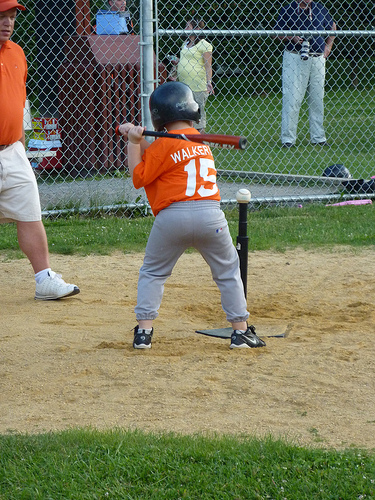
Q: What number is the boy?
A: 15.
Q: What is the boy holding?
A: A bat.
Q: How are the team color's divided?
A: Black helmet, orange shirts, gray pants.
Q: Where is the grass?
A: In front and behind the boy.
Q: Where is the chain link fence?
A: Between the players and spectators.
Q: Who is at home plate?
A: Walker.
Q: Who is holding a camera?
A: The man in the blue shirt.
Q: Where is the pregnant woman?
A: Near the brown structure.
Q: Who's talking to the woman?
A: A man.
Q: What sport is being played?
A: Softball.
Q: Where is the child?
A: Up to bat.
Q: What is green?
A: Grass.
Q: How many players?
A: One.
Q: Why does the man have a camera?
A: Taking pictures.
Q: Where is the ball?
A: On the tee.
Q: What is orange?
A: Shirt.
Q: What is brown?
A: Ground.